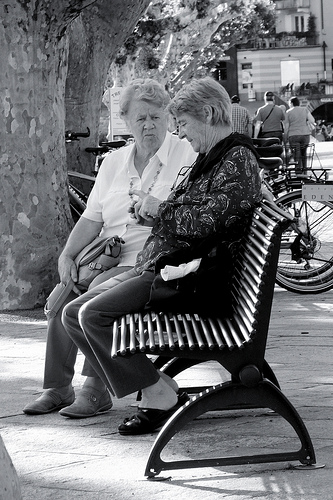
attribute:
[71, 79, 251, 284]
women — elderly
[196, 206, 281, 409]
bench — metal, on sidewalk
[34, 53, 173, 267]
first woman — looking perplexed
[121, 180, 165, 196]
necklace — beaded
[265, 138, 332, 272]
bike — parked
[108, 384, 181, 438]
shoe — clogs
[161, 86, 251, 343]
2nd woman — gesturing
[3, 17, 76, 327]
tree trunk — possible sycamore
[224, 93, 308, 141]
people — walking, walking down street, walking away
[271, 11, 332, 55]
building — in background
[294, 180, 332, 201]
sign — halved, white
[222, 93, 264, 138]
guy — showing his back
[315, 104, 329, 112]
dark entrance — to tunnel